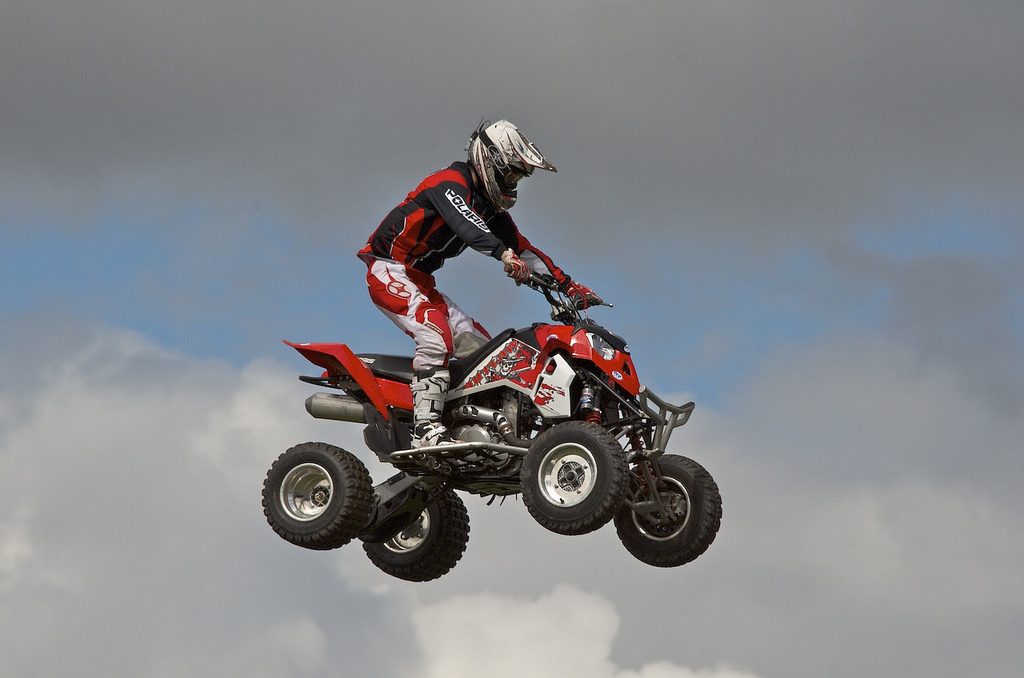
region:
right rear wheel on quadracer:
[258, 439, 376, 551]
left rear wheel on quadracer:
[361, 474, 470, 580]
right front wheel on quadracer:
[520, 420, 631, 535]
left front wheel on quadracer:
[611, 448, 725, 567]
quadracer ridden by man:
[260, 312, 728, 584]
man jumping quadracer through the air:
[352, 116, 603, 452]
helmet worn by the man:
[472, 117, 561, 213]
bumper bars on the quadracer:
[636, 382, 698, 455]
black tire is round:
[529, 424, 619, 532]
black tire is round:
[617, 453, 719, 564]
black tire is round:
[262, 442, 364, 551]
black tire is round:
[361, 480, 469, 580]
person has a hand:
[496, 254, 535, 278]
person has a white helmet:
[471, 113, 547, 209]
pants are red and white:
[367, 256, 492, 434]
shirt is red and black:
[367, 164, 514, 288]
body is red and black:
[288, 318, 646, 435]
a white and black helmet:
[470, 116, 559, 212]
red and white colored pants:
[363, 260, 496, 445]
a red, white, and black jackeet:
[357, 160, 582, 303]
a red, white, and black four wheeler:
[262, 266, 725, 583]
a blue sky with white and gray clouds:
[3, 0, 1021, 675]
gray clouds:
[3, 2, 1019, 247]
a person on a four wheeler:
[264, 117, 720, 567]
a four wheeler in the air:
[256, 256, 727, 582]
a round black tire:
[522, 418, 627, 539]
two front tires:
[518, 423, 722, 572]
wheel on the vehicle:
[487, 392, 650, 551]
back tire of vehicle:
[218, 421, 377, 574]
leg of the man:
[322, 246, 503, 481]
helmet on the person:
[438, 98, 568, 236]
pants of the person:
[316, 215, 500, 466]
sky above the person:
[18, 94, 287, 414]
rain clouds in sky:
[63, 16, 759, 152]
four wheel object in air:
[233, 269, 709, 630]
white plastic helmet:
[459, 97, 562, 215]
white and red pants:
[355, 256, 510, 440]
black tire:
[517, 417, 617, 529]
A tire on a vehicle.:
[517, 430, 626, 536]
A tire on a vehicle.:
[626, 460, 718, 563]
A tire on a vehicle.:
[376, 481, 462, 570]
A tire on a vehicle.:
[256, 446, 392, 560]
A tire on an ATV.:
[253, 443, 362, 546]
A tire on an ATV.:
[362, 482, 446, 575]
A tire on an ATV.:
[521, 422, 605, 527]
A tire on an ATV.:
[620, 463, 715, 553]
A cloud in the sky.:
[408, 582, 681, 675]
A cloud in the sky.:
[272, 611, 329, 647]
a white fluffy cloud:
[643, 230, 941, 420]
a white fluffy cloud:
[848, 405, 956, 542]